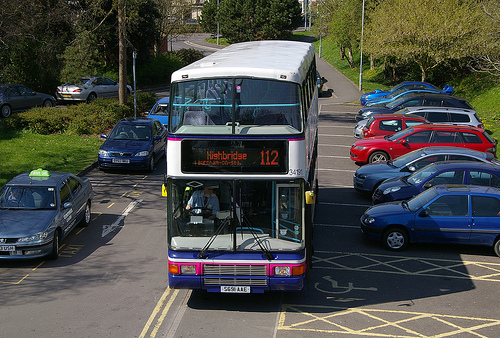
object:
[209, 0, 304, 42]
green leaves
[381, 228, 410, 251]
tire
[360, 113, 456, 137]
cars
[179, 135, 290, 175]
sign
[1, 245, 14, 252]
white licenseplate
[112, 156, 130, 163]
white licenseplate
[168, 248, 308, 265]
white strip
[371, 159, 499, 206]
car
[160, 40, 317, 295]
grey stone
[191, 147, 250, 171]
words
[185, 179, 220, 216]
driver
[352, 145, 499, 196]
car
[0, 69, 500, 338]
parking lot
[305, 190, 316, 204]
left mirror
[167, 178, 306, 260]
windshield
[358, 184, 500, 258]
blue car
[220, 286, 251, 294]
license plate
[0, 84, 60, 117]
car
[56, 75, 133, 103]
car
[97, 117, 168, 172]
car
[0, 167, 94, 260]
car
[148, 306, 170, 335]
line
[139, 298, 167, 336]
line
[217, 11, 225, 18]
leaf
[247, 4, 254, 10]
leaf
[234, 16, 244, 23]
leaf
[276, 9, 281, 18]
leaf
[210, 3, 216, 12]
leaf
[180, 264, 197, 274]
headlight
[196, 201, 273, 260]
windshield wiper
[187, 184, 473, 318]
shadow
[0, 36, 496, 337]
ground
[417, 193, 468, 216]
window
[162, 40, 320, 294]
bus